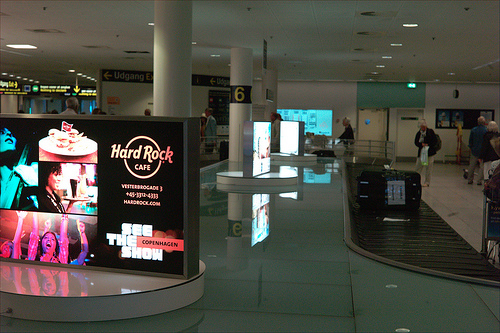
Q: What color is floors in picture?
A: Green.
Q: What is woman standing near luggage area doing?
A: Looking at her watch.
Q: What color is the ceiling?
A: White.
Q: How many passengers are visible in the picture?
A: Nine.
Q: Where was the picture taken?
A: In airport near baggage area.